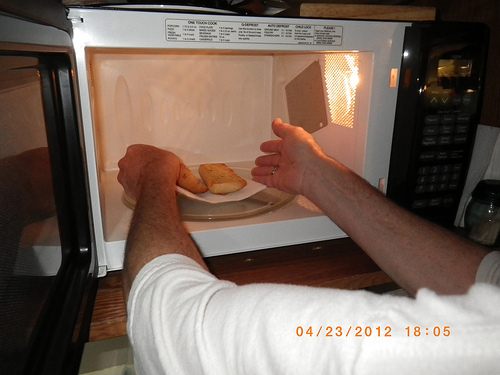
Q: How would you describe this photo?
A: A person heating food.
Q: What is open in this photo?
A: A microwave door.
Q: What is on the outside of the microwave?
A: Buttons.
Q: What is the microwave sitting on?
A: A brown wooden countertop.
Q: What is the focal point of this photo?
A: A black and white microwave.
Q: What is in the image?
A: Pair of two hands.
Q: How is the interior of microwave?
A: White.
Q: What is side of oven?
A: Black panel.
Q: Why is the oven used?
A: Reheat.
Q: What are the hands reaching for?
A: Food.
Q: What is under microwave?
A: Wood surface.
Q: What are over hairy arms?
A: White sleeves.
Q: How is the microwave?
A: Open door.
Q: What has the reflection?
A: Window.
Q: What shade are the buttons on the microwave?
A: Black.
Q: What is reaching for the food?
A: Two hands.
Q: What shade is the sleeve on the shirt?
A: White.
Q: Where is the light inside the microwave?
A: On the right.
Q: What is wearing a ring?
A: The hand.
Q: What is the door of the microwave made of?
A: Glass.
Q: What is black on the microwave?
A: Control panel.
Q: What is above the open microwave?
A: Heating directions.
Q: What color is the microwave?
A: Black.